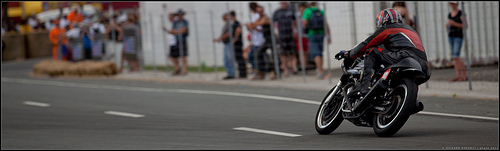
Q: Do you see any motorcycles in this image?
A: Yes, there is a motorcycle.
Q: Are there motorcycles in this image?
A: Yes, there is a motorcycle.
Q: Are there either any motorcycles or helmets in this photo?
A: Yes, there is a motorcycle.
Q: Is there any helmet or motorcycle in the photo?
A: Yes, there is a motorcycle.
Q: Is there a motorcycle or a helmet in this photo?
A: Yes, there is a motorcycle.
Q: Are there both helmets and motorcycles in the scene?
A: Yes, there are both a motorcycle and a helmet.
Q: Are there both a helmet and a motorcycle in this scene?
A: Yes, there are both a motorcycle and a helmet.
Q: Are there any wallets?
A: No, there are no wallets.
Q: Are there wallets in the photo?
A: No, there are no wallets.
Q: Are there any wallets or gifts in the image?
A: No, there are no wallets or gifts.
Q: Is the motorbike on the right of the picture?
A: Yes, the motorbike is on the right of the image.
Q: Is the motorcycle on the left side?
A: No, the motorcycle is on the right of the image.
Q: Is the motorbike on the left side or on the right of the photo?
A: The motorbike is on the right of the image.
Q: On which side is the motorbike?
A: The motorbike is on the right of the image.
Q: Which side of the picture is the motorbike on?
A: The motorbike is on the right of the image.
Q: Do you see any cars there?
A: No, there are no cars.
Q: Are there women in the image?
A: Yes, there is a woman.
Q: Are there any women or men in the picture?
A: Yes, there is a woman.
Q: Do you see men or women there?
A: Yes, there is a woman.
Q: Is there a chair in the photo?
A: No, there are no chairs.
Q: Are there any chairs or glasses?
A: No, there are no chairs or glasses.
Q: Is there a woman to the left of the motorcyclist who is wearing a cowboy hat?
A: Yes, there is a woman to the left of the biker.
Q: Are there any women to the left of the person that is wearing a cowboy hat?
A: Yes, there is a woman to the left of the biker.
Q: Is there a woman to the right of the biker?
A: No, the woman is to the left of the biker.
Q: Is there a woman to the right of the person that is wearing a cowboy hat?
A: No, the woman is to the left of the biker.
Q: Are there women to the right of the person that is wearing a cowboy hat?
A: No, the woman is to the left of the biker.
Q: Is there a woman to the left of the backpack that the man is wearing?
A: Yes, there is a woman to the left of the backpack.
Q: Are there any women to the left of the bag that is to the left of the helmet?
A: Yes, there is a woman to the left of the backpack.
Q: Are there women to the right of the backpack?
A: No, the woman is to the left of the backpack.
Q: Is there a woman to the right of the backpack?
A: No, the woman is to the left of the backpack.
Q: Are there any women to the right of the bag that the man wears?
A: No, the woman is to the left of the backpack.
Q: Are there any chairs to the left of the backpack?
A: No, there is a woman to the left of the backpack.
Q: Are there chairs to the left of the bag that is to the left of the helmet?
A: No, there is a woman to the left of the backpack.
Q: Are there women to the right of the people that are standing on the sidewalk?
A: Yes, there is a woman to the right of the people.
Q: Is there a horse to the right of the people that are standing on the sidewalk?
A: No, there is a woman to the right of the people.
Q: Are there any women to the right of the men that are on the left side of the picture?
A: Yes, there is a woman to the right of the men.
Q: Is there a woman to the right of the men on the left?
A: Yes, there is a woman to the right of the men.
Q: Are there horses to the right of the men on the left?
A: No, there is a woman to the right of the men.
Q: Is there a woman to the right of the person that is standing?
A: Yes, there is a woman to the right of the person.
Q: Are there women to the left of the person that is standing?
A: No, the woman is to the right of the person.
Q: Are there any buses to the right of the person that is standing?
A: No, there is a woman to the right of the person.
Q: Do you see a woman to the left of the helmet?
A: Yes, there is a woman to the left of the helmet.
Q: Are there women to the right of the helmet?
A: No, the woman is to the left of the helmet.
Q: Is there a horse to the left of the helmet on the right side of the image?
A: No, there is a woman to the left of the helmet.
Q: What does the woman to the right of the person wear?
A: The woman wears a shirt.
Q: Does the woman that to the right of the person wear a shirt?
A: Yes, the woman wears a shirt.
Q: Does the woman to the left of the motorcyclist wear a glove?
A: No, the woman wears a shirt.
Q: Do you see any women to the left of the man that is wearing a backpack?
A: Yes, there is a woman to the left of the man.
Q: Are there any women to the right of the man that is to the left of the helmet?
A: No, the woman is to the left of the man.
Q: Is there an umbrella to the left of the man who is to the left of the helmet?
A: No, there is a woman to the left of the man.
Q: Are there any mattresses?
A: No, there are no mattresses.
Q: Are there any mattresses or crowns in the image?
A: No, there are no mattresses or crowns.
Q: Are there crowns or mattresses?
A: No, there are no mattresses or crowns.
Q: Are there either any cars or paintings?
A: No, there are no cars or paintings.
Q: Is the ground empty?
A: Yes, the ground is empty.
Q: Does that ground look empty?
A: Yes, the ground is empty.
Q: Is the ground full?
A: No, the ground is empty.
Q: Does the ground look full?
A: No, the ground is empty.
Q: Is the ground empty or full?
A: The ground is empty.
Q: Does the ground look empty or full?
A: The ground is empty.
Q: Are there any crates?
A: No, there are no crates.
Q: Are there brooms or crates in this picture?
A: No, there are no crates or brooms.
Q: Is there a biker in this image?
A: Yes, there is a biker.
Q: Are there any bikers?
A: Yes, there is a biker.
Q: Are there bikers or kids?
A: Yes, there is a biker.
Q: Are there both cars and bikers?
A: No, there is a biker but no cars.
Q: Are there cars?
A: No, there are no cars.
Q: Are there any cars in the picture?
A: No, there are no cars.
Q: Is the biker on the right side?
A: Yes, the biker is on the right of the image.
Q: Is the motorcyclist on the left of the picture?
A: No, the motorcyclist is on the right of the image.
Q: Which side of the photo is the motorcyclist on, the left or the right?
A: The motorcyclist is on the right of the image.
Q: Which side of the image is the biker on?
A: The biker is on the right of the image.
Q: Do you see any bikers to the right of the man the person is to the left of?
A: Yes, there is a biker to the right of the man.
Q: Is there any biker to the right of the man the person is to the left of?
A: Yes, there is a biker to the right of the man.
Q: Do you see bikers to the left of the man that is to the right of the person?
A: No, the biker is to the right of the man.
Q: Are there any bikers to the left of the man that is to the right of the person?
A: No, the biker is to the right of the man.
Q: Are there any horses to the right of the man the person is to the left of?
A: No, there is a biker to the right of the man.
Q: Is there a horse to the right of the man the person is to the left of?
A: No, there is a biker to the right of the man.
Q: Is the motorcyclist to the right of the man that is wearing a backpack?
A: Yes, the motorcyclist is to the right of the man.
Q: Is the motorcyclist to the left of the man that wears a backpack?
A: No, the motorcyclist is to the right of the man.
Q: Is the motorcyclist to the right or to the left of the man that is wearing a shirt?
A: The motorcyclist is to the right of the man.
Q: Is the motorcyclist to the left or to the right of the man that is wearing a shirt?
A: The motorcyclist is to the right of the man.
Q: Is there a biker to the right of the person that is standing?
A: Yes, there is a biker to the right of the person.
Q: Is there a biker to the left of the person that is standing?
A: No, the biker is to the right of the person.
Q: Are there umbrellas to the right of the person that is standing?
A: No, there is a biker to the right of the person.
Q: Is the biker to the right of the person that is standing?
A: Yes, the biker is to the right of the person.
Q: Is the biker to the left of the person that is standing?
A: No, the biker is to the right of the person.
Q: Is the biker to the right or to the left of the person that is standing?
A: The biker is to the right of the person.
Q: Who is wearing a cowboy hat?
A: The biker is wearing a cowboy hat.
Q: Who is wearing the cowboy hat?
A: The biker is wearing a cowboy hat.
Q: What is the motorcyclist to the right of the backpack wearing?
A: The motorcyclist is wearing a cowboy hat.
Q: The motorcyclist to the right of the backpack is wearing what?
A: The motorcyclist is wearing a cowboy hat.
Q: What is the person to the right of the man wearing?
A: The motorcyclist is wearing a cowboy hat.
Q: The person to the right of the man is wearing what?
A: The motorcyclist is wearing a cowboy hat.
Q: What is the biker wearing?
A: The motorcyclist is wearing a cowboy hat.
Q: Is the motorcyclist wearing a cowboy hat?
A: Yes, the motorcyclist is wearing a cowboy hat.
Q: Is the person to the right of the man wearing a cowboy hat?
A: Yes, the motorcyclist is wearing a cowboy hat.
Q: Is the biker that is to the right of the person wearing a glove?
A: No, the biker is wearing a cowboy hat.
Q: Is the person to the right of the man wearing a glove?
A: No, the biker is wearing a cowboy hat.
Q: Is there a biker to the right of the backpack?
A: Yes, there is a biker to the right of the backpack.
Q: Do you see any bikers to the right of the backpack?
A: Yes, there is a biker to the right of the backpack.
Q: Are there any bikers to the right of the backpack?
A: Yes, there is a biker to the right of the backpack.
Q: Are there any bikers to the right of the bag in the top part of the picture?
A: Yes, there is a biker to the right of the backpack.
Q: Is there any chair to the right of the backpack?
A: No, there is a biker to the right of the backpack.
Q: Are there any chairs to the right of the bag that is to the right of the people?
A: No, there is a biker to the right of the backpack.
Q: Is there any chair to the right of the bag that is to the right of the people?
A: No, there is a biker to the right of the backpack.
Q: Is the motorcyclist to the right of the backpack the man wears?
A: Yes, the motorcyclist is to the right of the backpack.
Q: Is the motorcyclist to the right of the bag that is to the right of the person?
A: Yes, the motorcyclist is to the right of the backpack.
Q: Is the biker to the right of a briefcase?
A: No, the biker is to the right of the backpack.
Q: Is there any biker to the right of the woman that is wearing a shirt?
A: Yes, there is a biker to the right of the woman.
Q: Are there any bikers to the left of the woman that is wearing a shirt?
A: No, the biker is to the right of the woman.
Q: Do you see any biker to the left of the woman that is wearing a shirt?
A: No, the biker is to the right of the woman.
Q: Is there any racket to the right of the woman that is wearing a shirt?
A: No, there is a biker to the right of the woman.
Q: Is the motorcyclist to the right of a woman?
A: Yes, the motorcyclist is to the right of a woman.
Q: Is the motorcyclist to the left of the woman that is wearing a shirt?
A: No, the motorcyclist is to the right of the woman.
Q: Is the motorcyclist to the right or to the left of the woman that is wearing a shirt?
A: The motorcyclist is to the right of the woman.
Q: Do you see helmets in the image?
A: Yes, there is a helmet.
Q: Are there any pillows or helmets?
A: Yes, there is a helmet.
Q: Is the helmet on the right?
A: Yes, the helmet is on the right of the image.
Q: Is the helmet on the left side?
A: No, the helmet is on the right of the image.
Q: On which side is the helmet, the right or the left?
A: The helmet is on the right of the image.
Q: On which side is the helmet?
A: The helmet is on the right of the image.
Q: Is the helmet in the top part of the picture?
A: Yes, the helmet is in the top of the image.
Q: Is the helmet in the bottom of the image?
A: No, the helmet is in the top of the image.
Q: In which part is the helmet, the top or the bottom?
A: The helmet is in the top of the image.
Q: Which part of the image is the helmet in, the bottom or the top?
A: The helmet is in the top of the image.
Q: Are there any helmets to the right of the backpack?
A: Yes, there is a helmet to the right of the backpack.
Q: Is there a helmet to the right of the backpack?
A: Yes, there is a helmet to the right of the backpack.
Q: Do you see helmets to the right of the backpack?
A: Yes, there is a helmet to the right of the backpack.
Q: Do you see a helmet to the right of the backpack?
A: Yes, there is a helmet to the right of the backpack.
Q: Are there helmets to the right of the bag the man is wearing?
A: Yes, there is a helmet to the right of the backpack.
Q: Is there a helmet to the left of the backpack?
A: No, the helmet is to the right of the backpack.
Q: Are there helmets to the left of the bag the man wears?
A: No, the helmet is to the right of the backpack.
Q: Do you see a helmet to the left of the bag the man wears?
A: No, the helmet is to the right of the backpack.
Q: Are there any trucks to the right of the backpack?
A: No, there is a helmet to the right of the backpack.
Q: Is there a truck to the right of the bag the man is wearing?
A: No, there is a helmet to the right of the backpack.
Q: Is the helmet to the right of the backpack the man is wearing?
A: Yes, the helmet is to the right of the backpack.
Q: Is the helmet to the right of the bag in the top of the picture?
A: Yes, the helmet is to the right of the backpack.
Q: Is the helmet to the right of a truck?
A: No, the helmet is to the right of the backpack.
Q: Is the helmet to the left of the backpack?
A: No, the helmet is to the right of the backpack.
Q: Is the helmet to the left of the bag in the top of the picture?
A: No, the helmet is to the right of the backpack.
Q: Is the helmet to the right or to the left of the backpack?
A: The helmet is to the right of the backpack.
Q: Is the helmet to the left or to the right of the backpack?
A: The helmet is to the right of the backpack.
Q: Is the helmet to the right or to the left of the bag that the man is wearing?
A: The helmet is to the right of the backpack.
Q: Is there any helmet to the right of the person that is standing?
A: Yes, there is a helmet to the right of the person.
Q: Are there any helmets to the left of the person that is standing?
A: No, the helmet is to the right of the person.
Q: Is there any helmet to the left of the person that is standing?
A: No, the helmet is to the right of the person.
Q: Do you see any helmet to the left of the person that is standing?
A: No, the helmet is to the right of the person.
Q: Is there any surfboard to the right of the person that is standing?
A: No, there is a helmet to the right of the person.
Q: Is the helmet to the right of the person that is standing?
A: Yes, the helmet is to the right of the person.